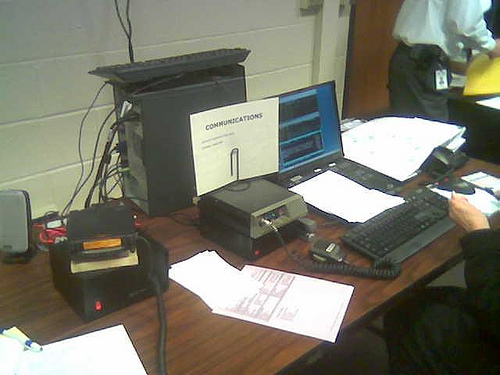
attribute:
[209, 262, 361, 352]
paper — white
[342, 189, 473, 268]
keyboard — black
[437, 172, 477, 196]
mouse — black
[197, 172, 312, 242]
cb radio — grey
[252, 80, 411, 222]
laptop — on, black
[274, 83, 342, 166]
computer screen — black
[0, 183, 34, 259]
speaker — grey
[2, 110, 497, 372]
desk — wooden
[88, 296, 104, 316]
switch — red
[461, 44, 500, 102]
folder — yellow, large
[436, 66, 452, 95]
id badge — white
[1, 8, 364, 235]
wall — white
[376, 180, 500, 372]
man — person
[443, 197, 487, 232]
hand — white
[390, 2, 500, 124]
man — standing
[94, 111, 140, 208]
electrical line — long, cable